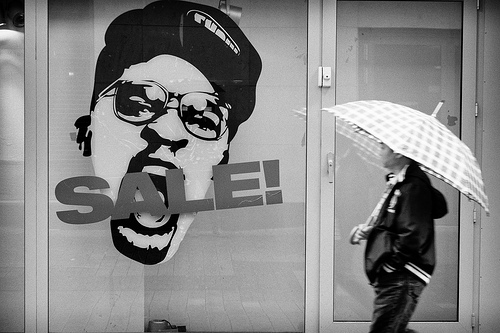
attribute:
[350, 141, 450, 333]
person — walking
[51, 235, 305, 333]
brick — reflecting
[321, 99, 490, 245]
umbrella — large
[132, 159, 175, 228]
mouth — open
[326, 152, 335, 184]
knob — silver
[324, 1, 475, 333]
door — glass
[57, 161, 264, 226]
letters — large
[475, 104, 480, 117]
hinge — metal